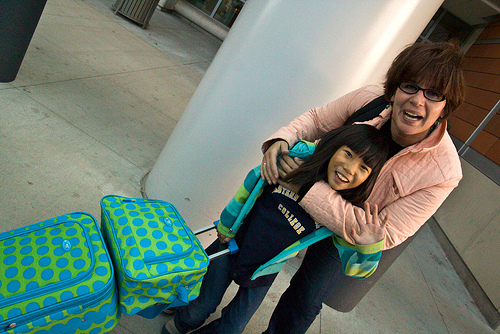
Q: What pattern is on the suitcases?
A: Polka dots.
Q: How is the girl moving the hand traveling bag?
A: Rolling on top of a luggage.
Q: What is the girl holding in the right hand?
A: The handle of a luggage.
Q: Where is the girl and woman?
A: An airport.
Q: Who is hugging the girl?
A: The grandmother.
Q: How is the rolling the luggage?
A: Pulling on wheels.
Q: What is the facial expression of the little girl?
A: Happiness.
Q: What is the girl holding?
A: Green and blue luggage.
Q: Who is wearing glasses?
A: Woman in peach coat.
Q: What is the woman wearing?
A: Peach jacket.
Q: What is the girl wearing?
A: Striped sweater and shirt.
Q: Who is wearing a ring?
A: The woman.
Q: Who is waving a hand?
A: The girl.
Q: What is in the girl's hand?
A: Luggage handle.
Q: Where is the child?
A: By the woman.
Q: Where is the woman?
A: By the child.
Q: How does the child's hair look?
A: Long.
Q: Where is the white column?
A: Behind the people.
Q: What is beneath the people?
A: Concrete.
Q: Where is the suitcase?
A: In front of the child.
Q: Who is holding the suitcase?
A: The child.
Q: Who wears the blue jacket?
A: The child.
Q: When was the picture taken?
A: During the day.